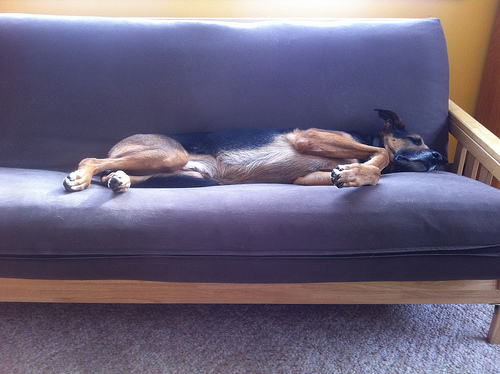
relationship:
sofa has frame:
[0, 10, 499, 347] [1, 276, 496, 305]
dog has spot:
[63, 106, 443, 199] [162, 127, 277, 158]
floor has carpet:
[0, 299, 499, 372] [2, 300, 498, 370]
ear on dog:
[373, 106, 405, 129] [63, 106, 443, 199]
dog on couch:
[63, 106, 443, 199] [28, 10, 473, 301]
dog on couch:
[63, 106, 443, 199] [0, 17, 499, 344]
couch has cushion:
[0, 17, 499, 344] [2, 12, 498, 279]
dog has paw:
[63, 106, 443, 199] [327, 161, 382, 188]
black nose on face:
[425, 150, 442, 163] [389, 127, 441, 171]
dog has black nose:
[63, 106, 443, 199] [425, 150, 442, 163]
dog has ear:
[63, 106, 443, 199] [374, 105, 410, 130]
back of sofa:
[0, 13, 452, 160] [0, 10, 499, 347]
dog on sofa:
[63, 106, 443, 199] [4, 12, 484, 323]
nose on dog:
[428, 148, 445, 164] [76, 77, 472, 247]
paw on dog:
[63, 171, 93, 191] [63, 106, 443, 199]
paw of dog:
[103, 168, 134, 199] [55, 100, 450, 198]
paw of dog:
[326, 158, 361, 189] [55, 100, 450, 198]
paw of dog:
[63, 171, 93, 191] [55, 100, 450, 198]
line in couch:
[4, 240, 484, 263] [0, 17, 499, 344]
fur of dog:
[198, 125, 259, 163] [50, 103, 456, 183]